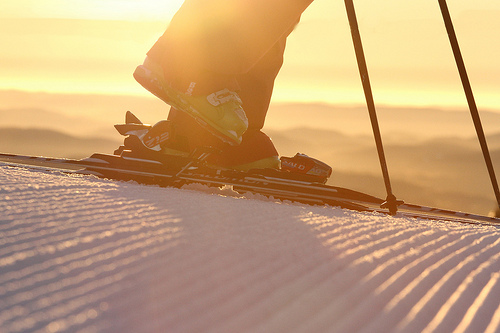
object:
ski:
[0, 152, 499, 226]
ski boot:
[132, 44, 250, 147]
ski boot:
[162, 129, 280, 174]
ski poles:
[344, 0, 405, 214]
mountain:
[0, 90, 499, 332]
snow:
[0, 161, 499, 332]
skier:
[132, 0, 317, 174]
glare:
[108, 0, 186, 22]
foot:
[133, 41, 248, 147]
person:
[132, 0, 316, 172]